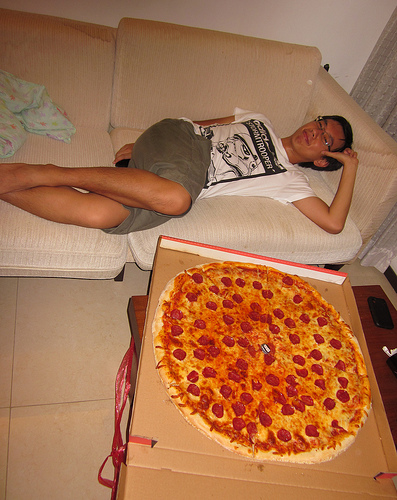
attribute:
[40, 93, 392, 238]
man — laying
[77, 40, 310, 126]
couch — beige, tan, white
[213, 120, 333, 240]
shirt — white, black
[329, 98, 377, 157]
hair — black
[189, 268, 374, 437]
pizza — big, pepperoni, large, brown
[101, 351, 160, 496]
strings — hanging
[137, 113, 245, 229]
shorts — gray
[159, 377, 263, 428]
cheese — burnt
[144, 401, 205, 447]
box — brown, filled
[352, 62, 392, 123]
curtain — grey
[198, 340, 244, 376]
pepperoni — sliced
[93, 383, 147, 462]
ribbon — red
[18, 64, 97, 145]
clothing — green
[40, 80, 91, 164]
blankets — thin